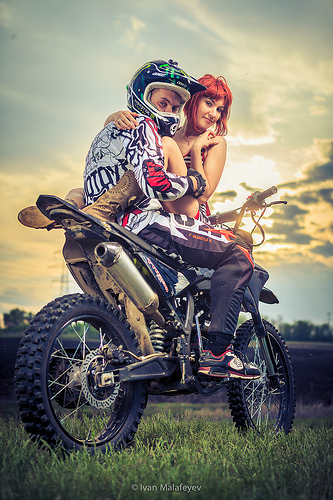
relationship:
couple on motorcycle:
[17, 53, 243, 258] [13, 183, 312, 456]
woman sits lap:
[170, 74, 232, 223] [144, 206, 258, 265]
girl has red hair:
[170, 74, 232, 223] [187, 72, 239, 137]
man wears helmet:
[67, 46, 194, 231] [118, 52, 206, 137]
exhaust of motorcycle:
[86, 235, 165, 330] [13, 183, 312, 456]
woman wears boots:
[170, 74, 232, 223] [19, 169, 143, 249]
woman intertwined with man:
[170, 74, 232, 223] [67, 46, 194, 231]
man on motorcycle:
[67, 46, 194, 231] [13, 183, 312, 456]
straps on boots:
[105, 192, 138, 220] [19, 169, 143, 249]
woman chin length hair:
[170, 74, 232, 223] [187, 72, 239, 137]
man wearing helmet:
[67, 46, 194, 231] [118, 52, 206, 137]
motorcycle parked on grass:
[13, 183, 312, 456] [6, 389, 323, 499]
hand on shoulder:
[101, 104, 149, 143] [90, 103, 130, 129]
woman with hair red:
[170, 74, 232, 223] [187, 72, 239, 137]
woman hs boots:
[170, 74, 232, 223] [19, 169, 143, 249]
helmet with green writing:
[118, 52, 206, 137] [159, 59, 189, 85]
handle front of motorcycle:
[249, 181, 279, 211] [13, 183, 312, 456]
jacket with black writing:
[78, 111, 195, 235] [67, 159, 126, 196]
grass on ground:
[6, 389, 323, 499] [3, 331, 331, 497]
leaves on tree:
[3, 307, 25, 326] [5, 298, 35, 332]